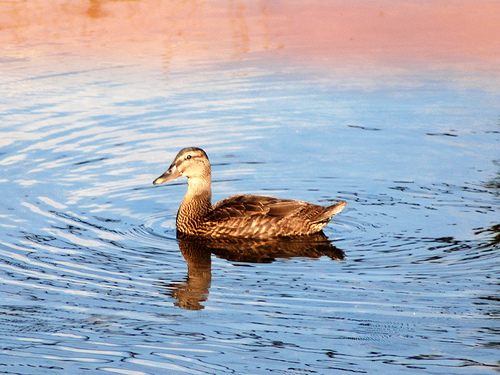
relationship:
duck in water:
[148, 144, 350, 246] [3, 1, 499, 372]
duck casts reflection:
[148, 144, 350, 246] [155, 232, 351, 317]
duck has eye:
[148, 144, 350, 246] [186, 153, 193, 160]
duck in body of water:
[148, 144, 350, 246] [3, 40, 498, 374]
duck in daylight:
[148, 144, 350, 246] [0, 1, 499, 252]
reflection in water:
[155, 232, 351, 317] [3, 1, 499, 372]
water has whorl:
[3, 1, 499, 372] [0, 115, 500, 375]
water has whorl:
[3, 1, 499, 372] [142, 208, 371, 251]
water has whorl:
[3, 1, 499, 372] [102, 184, 410, 269]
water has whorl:
[3, 1, 499, 372] [62, 115, 447, 304]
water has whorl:
[3, 1, 499, 372] [20, 103, 491, 334]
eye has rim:
[186, 153, 193, 160] [184, 152, 193, 162]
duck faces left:
[148, 144, 350, 246] [3, 1, 260, 374]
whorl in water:
[0, 115, 500, 375] [3, 1, 499, 372]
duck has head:
[148, 144, 350, 246] [151, 141, 217, 190]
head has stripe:
[151, 141, 217, 190] [169, 152, 211, 167]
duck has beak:
[148, 144, 350, 246] [150, 162, 182, 190]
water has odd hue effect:
[3, 1, 499, 372] [2, 2, 499, 118]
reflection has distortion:
[155, 232, 351, 317] [157, 271, 223, 317]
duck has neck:
[148, 144, 350, 246] [179, 178, 217, 210]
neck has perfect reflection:
[179, 178, 217, 210] [175, 241, 214, 270]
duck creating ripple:
[148, 144, 350, 246] [0, 57, 500, 375]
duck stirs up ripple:
[148, 144, 350, 246] [131, 198, 380, 266]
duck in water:
[152, 146, 348, 243] [3, 1, 499, 372]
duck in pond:
[152, 146, 348, 243] [2, 67, 498, 375]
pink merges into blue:
[1, 2, 499, 78] [2, 58, 499, 374]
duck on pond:
[148, 144, 350, 246] [2, 67, 498, 375]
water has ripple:
[3, 1, 499, 372] [0, 57, 500, 375]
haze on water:
[2, 46, 499, 106] [3, 1, 499, 372]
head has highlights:
[151, 141, 217, 190] [173, 140, 213, 181]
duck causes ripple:
[148, 144, 350, 246] [0, 57, 500, 375]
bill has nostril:
[150, 162, 182, 190] [166, 168, 175, 176]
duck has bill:
[148, 144, 350, 246] [149, 163, 183, 188]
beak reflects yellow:
[150, 162, 182, 190] [150, 174, 168, 187]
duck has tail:
[148, 144, 350, 246] [318, 197, 349, 229]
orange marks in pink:
[72, 1, 140, 26] [1, 2, 499, 78]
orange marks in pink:
[0, 0, 500, 96] [1, 2, 499, 78]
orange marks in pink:
[7, 22, 100, 46] [1, 2, 499, 78]